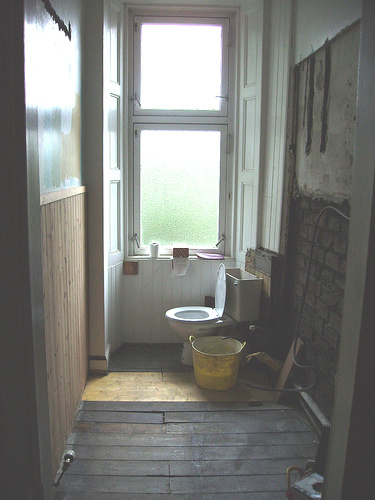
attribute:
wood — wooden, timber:
[29, 186, 92, 499]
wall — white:
[4, 0, 95, 500]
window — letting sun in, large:
[126, 10, 231, 264]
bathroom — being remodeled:
[3, 0, 374, 499]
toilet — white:
[166, 262, 261, 370]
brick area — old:
[275, 189, 350, 436]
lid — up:
[210, 262, 228, 316]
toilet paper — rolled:
[149, 241, 161, 261]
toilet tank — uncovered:
[225, 266, 265, 328]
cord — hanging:
[242, 205, 350, 393]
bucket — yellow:
[177, 334, 254, 398]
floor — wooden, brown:
[61, 342, 329, 499]